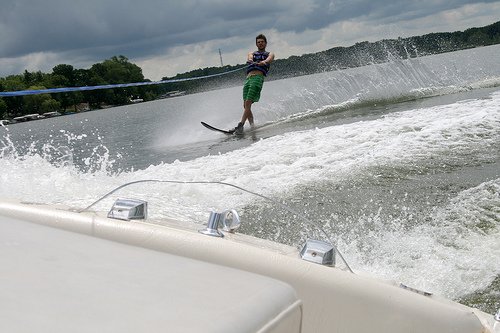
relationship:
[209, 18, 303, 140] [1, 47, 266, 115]
man using rope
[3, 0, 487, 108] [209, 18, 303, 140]
trees behind man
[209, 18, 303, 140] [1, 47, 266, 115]
man close to rope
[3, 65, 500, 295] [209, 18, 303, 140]
water below man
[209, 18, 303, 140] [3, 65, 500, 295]
man above water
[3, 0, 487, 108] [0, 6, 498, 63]
trees below sky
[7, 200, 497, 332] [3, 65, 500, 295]
boat close to water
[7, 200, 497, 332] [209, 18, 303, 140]
boat beside man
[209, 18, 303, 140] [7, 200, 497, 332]
man beside boat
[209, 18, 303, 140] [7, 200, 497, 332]
man close to boat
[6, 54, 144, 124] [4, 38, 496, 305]
trees near water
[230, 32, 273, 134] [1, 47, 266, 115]
skier holding rope